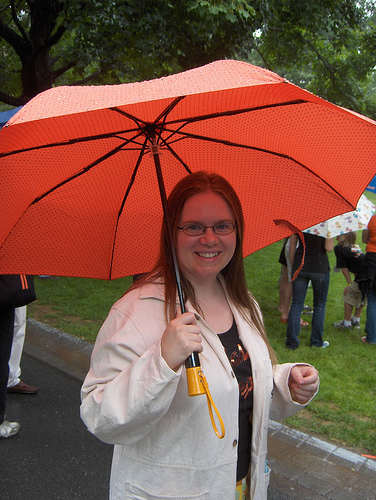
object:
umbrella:
[2, 58, 376, 439]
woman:
[79, 168, 321, 500]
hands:
[162, 311, 205, 373]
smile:
[185, 242, 229, 265]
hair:
[120, 174, 278, 370]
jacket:
[79, 260, 321, 498]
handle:
[185, 352, 210, 397]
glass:
[174, 216, 237, 237]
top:
[214, 317, 254, 480]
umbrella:
[302, 193, 375, 240]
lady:
[287, 230, 336, 350]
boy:
[333, 231, 369, 329]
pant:
[7, 303, 30, 387]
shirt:
[213, 317, 251, 480]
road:
[17, 349, 91, 481]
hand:
[162, 308, 205, 367]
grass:
[60, 289, 92, 323]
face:
[178, 194, 238, 276]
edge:
[24, 342, 82, 390]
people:
[362, 215, 376, 342]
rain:
[32, 20, 304, 94]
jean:
[285, 271, 330, 349]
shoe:
[11, 378, 41, 396]